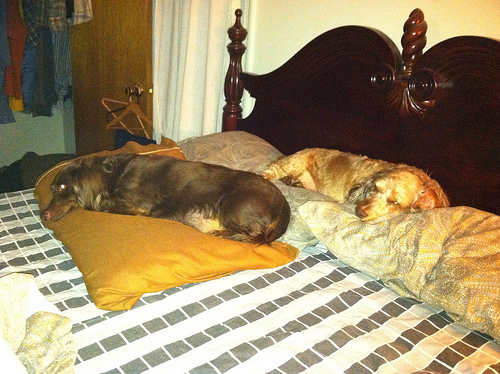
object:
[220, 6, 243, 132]
bedpost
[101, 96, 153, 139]
hangers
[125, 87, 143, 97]
doorknob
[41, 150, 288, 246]
dog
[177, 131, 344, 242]
pillow case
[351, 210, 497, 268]
pillow case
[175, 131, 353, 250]
pillow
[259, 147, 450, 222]
dog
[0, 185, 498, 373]
bedspread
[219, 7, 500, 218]
headboard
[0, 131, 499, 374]
bed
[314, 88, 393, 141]
wood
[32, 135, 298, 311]
pillow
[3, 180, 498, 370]
comforter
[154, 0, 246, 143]
curtains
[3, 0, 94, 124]
clothing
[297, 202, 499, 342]
pillow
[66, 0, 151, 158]
door